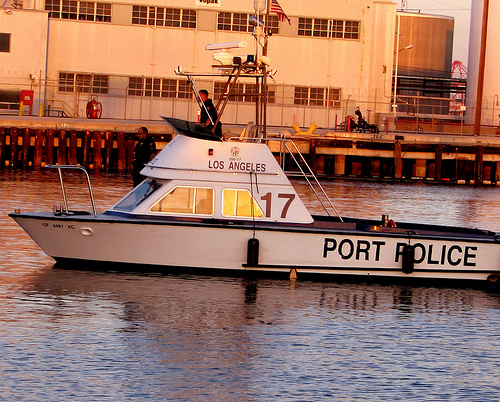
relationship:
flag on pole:
[269, 0, 292, 25] [262, 0, 270, 144]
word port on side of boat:
[322, 236, 388, 262] [6, 0, 499, 294]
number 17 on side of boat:
[259, 191, 297, 219] [6, 0, 499, 294]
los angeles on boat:
[207, 159, 267, 173] [6, 0, 499, 294]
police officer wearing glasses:
[132, 125, 157, 188] [135, 131, 148, 135]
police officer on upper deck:
[196, 88, 224, 141] [137, 114, 298, 186]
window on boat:
[148, 184, 217, 217] [6, 0, 499, 294]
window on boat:
[220, 187, 266, 220] [6, 0, 499, 294]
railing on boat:
[43, 163, 98, 216] [6, 0, 499, 294]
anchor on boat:
[245, 237, 261, 269] [6, 0, 499, 294]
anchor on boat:
[401, 243, 415, 274] [6, 0, 499, 294]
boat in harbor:
[6, 0, 499, 294] [3, 110, 499, 189]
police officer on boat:
[196, 88, 224, 141] [6, 0, 499, 294]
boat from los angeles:
[6, 0, 499, 294] [207, 159, 267, 173]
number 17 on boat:
[259, 191, 297, 219] [6, 0, 499, 294]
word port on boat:
[322, 236, 388, 262] [6, 0, 499, 294]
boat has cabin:
[6, 0, 499, 294] [103, 175, 317, 223]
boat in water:
[6, 0, 499, 294] [1, 170, 498, 401]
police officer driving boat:
[132, 125, 157, 188] [6, 0, 499, 294]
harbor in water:
[3, 110, 499, 189] [1, 170, 498, 401]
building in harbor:
[2, 0, 400, 130] [3, 110, 499, 189]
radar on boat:
[203, 38, 251, 68] [6, 0, 499, 294]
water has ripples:
[1, 170, 498, 401] [320, 369, 400, 390]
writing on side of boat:
[321, 236, 479, 267] [6, 0, 499, 294]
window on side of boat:
[148, 184, 217, 217] [6, 0, 499, 294]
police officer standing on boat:
[132, 125, 157, 188] [6, 0, 499, 294]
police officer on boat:
[132, 125, 157, 188] [6, 0, 499, 294]